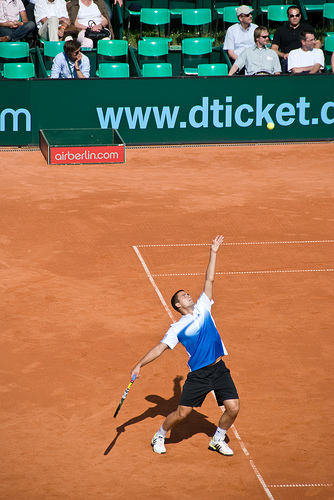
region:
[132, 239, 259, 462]
a man in black shorts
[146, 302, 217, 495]
a man in black shorts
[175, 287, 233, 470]
a man in black shorts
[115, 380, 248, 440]
player's shadow on the court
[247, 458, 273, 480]
white line on the red clay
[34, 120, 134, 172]
green box with red paint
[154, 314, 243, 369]
blue and white tennis shirt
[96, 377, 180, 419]
racket in player's hand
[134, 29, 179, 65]
shiny green seat in the stands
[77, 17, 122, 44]
black hand bag in woman's hand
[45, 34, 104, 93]
man's head turned to the side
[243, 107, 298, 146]
yellow tennis ball being thrown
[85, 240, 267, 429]
player on the court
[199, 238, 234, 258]
left hand of player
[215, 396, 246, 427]
left knee of player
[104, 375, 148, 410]
racquet of tennis player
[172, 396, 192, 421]
right knee of player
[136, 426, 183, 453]
right tennis shoe of player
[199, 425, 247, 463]
left shoe of player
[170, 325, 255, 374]
blue shirt of player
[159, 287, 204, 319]
head of tennis player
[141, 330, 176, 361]
right bicep of player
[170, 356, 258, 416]
black shorts of tennis player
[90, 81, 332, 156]
display of the advertisement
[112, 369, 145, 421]
a bat holding by person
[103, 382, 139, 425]
a shuttle bat holding by person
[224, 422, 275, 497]
a white line in ground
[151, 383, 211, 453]
shadow of the person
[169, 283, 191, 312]
face of the person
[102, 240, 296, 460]
a person in ground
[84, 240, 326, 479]
a boy trying to hit ball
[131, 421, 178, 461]
shoe of the person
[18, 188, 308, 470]
a clean brown ground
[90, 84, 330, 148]
a small display for advertisement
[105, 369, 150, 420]
shuttle bat holding by person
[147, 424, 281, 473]
shoes of the person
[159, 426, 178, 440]
socks of the person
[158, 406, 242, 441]
legs of the person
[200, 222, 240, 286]
hand of the person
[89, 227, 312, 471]
a person trying to play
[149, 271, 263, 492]
a white line on ground